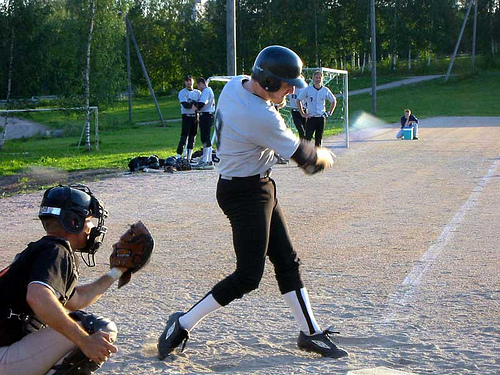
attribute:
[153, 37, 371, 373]
man — squatting, standing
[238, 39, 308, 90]
helmet — hard, black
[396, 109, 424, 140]
man — crouched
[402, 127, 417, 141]
water cooler — blue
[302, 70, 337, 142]
man — watching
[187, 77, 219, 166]
man — talking, facing, standing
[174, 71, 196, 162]
man — talking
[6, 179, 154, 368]
catcher — posed, crouched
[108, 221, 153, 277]
mitt — extended, leather, glove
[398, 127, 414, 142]
pitcher — teal green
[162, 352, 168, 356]
toe — pointed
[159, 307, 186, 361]
shoe — black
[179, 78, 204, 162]
player — facing, standing, talking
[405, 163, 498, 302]
line — drawn, chalked, white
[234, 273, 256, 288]
knee — bent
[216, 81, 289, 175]
jersey — gray, white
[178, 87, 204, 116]
jersey — gray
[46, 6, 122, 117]
tree — green, lush